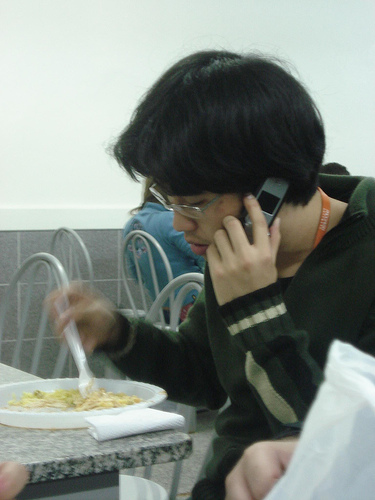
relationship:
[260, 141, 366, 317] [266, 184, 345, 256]
cord around neck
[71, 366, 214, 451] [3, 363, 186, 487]
napkin on table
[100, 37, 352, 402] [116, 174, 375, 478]
man on shirt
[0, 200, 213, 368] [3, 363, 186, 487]
chairs at table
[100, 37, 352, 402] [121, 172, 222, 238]
man has glasses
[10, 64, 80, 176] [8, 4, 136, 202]
blue on wall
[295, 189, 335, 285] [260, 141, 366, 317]
lanyard on neck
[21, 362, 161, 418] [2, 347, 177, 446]
food on plate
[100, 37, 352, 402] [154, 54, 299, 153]
man has hair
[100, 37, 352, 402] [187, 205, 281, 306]
person has finger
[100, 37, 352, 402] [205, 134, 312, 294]
man on phone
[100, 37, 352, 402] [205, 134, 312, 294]
man holding phone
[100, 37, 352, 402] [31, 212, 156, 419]
man holding fork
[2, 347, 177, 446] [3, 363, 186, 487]
plate in table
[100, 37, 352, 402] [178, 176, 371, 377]
man wearing shirt